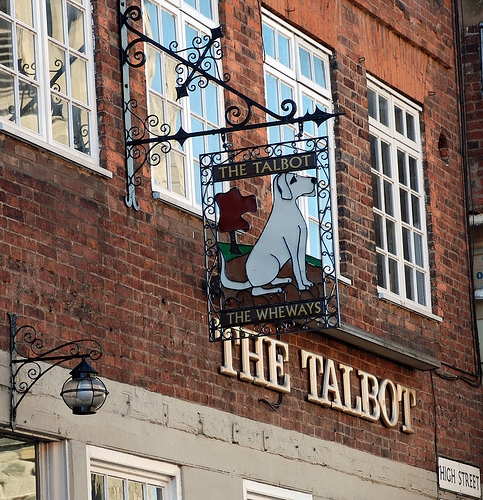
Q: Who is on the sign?
A: A dog.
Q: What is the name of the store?
A: The Talbot.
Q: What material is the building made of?
A: Brick.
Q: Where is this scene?
A: High Street.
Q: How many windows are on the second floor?
A: Four.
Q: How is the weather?
A: Sunny.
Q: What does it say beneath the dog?
A: The Wheways.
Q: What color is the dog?
A: White.